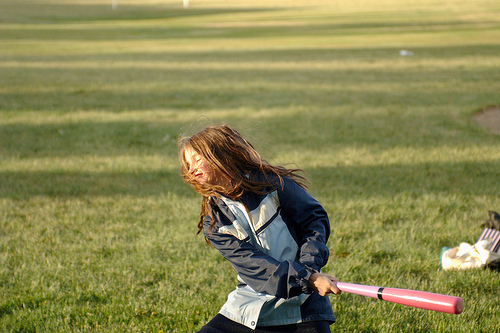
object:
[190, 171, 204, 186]
mouth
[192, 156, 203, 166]
eye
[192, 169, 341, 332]
body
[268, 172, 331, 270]
arm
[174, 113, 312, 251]
hair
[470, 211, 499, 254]
bag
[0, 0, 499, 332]
ground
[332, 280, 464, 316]
bat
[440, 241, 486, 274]
belongings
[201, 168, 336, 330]
coat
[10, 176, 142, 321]
grass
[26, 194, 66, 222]
sun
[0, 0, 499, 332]
park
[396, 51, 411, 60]
trash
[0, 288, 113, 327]
patch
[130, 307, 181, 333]
patch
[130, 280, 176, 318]
patch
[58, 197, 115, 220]
patch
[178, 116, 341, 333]
child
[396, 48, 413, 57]
patch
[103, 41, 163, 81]
patch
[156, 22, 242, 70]
patch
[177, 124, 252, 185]
head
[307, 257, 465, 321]
bat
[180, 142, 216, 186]
face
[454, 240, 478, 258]
bundle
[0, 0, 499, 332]
grass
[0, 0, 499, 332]
field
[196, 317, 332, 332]
pants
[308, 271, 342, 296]
hand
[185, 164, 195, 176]
nose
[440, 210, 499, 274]
group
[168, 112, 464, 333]
playing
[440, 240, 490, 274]
stuff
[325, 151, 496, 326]
grass